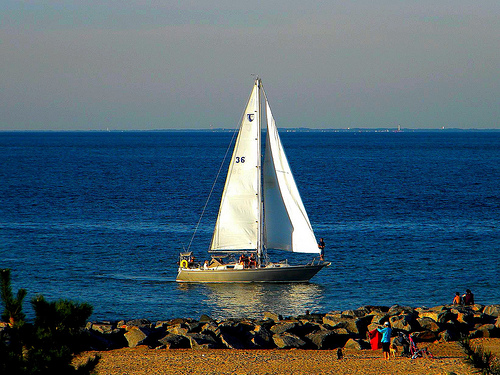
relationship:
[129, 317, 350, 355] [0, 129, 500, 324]
rocks front of ocean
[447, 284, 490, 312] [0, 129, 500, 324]
people near ocean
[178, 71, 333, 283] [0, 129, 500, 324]
sailboat in ocean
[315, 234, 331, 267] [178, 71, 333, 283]
person in sailboat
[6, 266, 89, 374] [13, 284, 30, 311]
tree has branch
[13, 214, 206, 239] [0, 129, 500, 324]
reflection in ocean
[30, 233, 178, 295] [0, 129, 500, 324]
waves in ocean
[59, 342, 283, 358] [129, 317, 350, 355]
grass by rocks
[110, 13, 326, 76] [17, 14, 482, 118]
clouds in sky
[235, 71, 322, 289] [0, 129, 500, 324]
sailboat in ocean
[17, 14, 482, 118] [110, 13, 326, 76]
sky has clouds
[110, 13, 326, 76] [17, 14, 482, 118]
clouds are in sky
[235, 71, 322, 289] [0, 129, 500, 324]
sailboat on top of ocean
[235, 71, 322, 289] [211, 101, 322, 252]
sailboat has masts